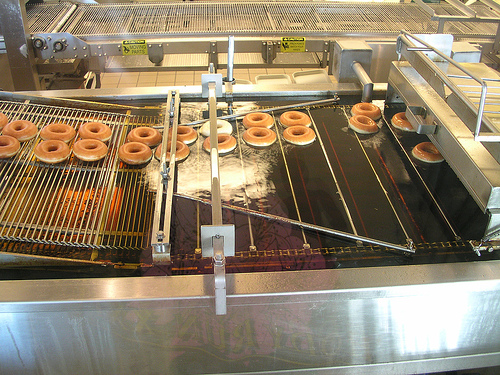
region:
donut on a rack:
[43, 117, 71, 142]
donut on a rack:
[35, 137, 70, 168]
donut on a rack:
[72, 118, 107, 137]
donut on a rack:
[75, 138, 106, 162]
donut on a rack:
[128, 121, 162, 146]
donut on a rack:
[117, 139, 149, 165]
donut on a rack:
[168, 121, 197, 144]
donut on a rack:
[153, 138, 189, 162]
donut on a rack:
[201, 135, 235, 157]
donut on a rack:
[241, 125, 273, 151]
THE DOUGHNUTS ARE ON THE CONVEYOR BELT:
[0, 77, 435, 172]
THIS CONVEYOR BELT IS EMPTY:
[17, 0, 497, 38]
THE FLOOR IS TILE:
[80, 60, 340, 85]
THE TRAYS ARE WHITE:
[247, 63, 342, 88]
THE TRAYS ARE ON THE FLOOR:
[255, 65, 340, 96]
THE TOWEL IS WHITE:
[398, 28, 458, 64]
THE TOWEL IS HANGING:
[398, 25, 465, 68]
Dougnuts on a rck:
[9, 103, 443, 213]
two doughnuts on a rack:
[109, 115, 154, 179]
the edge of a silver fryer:
[284, 267, 429, 334]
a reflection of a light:
[345, 295, 471, 368]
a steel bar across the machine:
[194, 53, 239, 285]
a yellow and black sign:
[268, 19, 315, 64]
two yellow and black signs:
[110, 18, 349, 74]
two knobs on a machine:
[18, 27, 81, 64]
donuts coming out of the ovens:
[173, 30, 498, 245]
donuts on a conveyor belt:
[1, 88, 197, 254]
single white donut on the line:
[196, 115, 232, 135]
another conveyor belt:
[0, 0, 496, 36]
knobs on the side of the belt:
[31, 35, 65, 55]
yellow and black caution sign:
[121, 39, 151, 57]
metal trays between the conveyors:
[233, 68, 335, 86]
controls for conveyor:
[328, 36, 374, 83]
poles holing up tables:
[226, 34, 237, 84]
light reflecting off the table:
[347, 279, 499, 357]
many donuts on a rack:
[11, 108, 356, 160]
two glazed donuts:
[283, 108, 315, 145]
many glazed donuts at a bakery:
[11, 110, 346, 173]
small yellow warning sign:
[119, 39, 162, 58]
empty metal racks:
[76, 4, 399, 47]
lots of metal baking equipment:
[52, 5, 424, 256]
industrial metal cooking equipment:
[66, 2, 392, 243]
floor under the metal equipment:
[102, 70, 194, 85]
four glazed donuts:
[41, 118, 106, 161]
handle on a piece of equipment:
[400, 103, 443, 130]